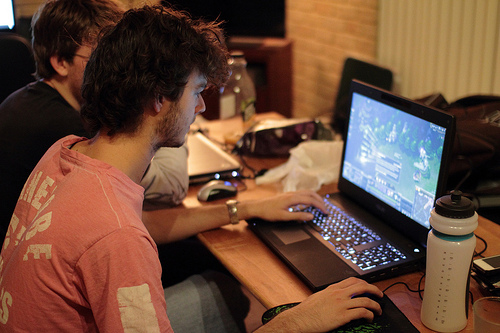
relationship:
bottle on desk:
[420, 189, 480, 331] [156, 107, 497, 324]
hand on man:
[287, 275, 384, 333] [0, 4, 387, 332]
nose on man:
[194, 95, 208, 115] [0, 4, 387, 332]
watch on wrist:
[225, 196, 240, 224] [223, 200, 251, 224]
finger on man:
[345, 294, 384, 311] [0, 4, 387, 332]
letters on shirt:
[3, 172, 58, 322] [0, 135, 173, 331]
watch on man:
[223, 198, 241, 225] [0, 4, 387, 332]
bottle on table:
[216, 47, 258, 151] [173, 105, 497, 329]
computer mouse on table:
[196, 177, 236, 201] [173, 105, 497, 329]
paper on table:
[267, 135, 332, 202] [180, 120, 493, 331]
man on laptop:
[14, 4, 256, 289] [246, 78, 457, 291]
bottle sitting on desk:
[221, 60, 285, 137] [156, 107, 497, 324]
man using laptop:
[0, 4, 387, 332] [316, 76, 456, 274]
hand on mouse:
[287, 275, 384, 333] [349, 278, 384, 327]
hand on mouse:
[355, 290, 384, 307] [349, 278, 384, 327]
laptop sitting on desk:
[246, 78, 457, 291] [156, 107, 497, 324]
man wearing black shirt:
[0, 0, 122, 250] [0, 80, 85, 225]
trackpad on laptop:
[264, 207, 317, 247] [239, 93, 479, 303]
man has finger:
[0, 4, 387, 332] [342, 286, 383, 314]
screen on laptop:
[345, 101, 430, 207] [246, 78, 456, 294]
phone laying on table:
[466, 252, 498, 287] [173, 105, 497, 329]